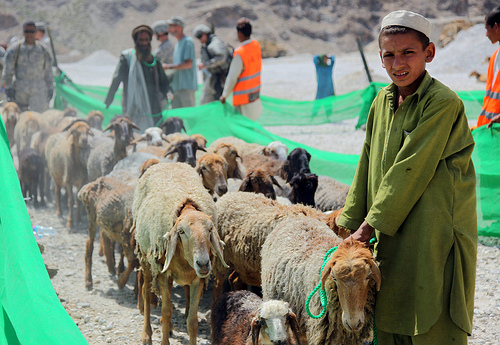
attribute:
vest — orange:
[232, 41, 260, 103]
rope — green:
[319, 250, 330, 323]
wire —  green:
[285, 244, 377, 298]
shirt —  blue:
[174, 36, 197, 91]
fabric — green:
[257, 74, 351, 135]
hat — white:
[377, 8, 433, 40]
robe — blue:
[312, 52, 336, 96]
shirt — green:
[330, 74, 495, 339]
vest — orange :
[221, 37, 263, 111]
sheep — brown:
[201, 288, 302, 343]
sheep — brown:
[211, 189, 345, 295]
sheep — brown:
[217, 132, 289, 179]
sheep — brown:
[128, 160, 223, 337]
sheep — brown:
[255, 214, 387, 344]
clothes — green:
[339, 78, 487, 342]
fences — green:
[255, 84, 367, 124]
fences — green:
[173, 98, 283, 147]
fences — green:
[44, 74, 130, 126]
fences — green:
[447, 84, 499, 235]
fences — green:
[0, 122, 89, 344]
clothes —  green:
[356, 148, 453, 263]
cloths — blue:
[369, 101, 479, 333]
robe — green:
[385, 94, 485, 341]